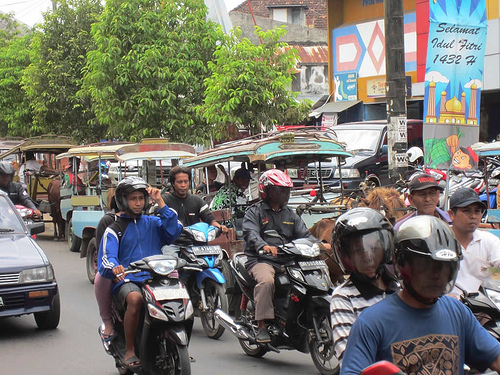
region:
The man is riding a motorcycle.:
[211, 167, 354, 369]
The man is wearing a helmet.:
[255, 165, 298, 215]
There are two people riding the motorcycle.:
[88, 172, 213, 374]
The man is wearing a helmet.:
[111, 178, 153, 218]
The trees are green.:
[0, 0, 306, 141]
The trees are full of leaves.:
[0, 1, 315, 151]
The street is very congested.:
[1, 135, 496, 373]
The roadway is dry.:
[0, 238, 322, 372]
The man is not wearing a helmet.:
[168, 162, 208, 200]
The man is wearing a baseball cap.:
[452, 187, 494, 232]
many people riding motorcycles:
[55, 139, 488, 351]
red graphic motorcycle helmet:
[237, 166, 290, 213]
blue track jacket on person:
[107, 197, 186, 287]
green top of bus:
[233, 134, 360, 164]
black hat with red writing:
[405, 168, 447, 213]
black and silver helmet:
[393, 209, 463, 306]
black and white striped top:
[328, 284, 355, 346]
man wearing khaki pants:
[237, 261, 283, 336]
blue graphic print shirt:
[353, 298, 488, 373]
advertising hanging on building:
[425, 16, 482, 86]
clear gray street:
[20, 328, 95, 361]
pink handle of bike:
[363, 351, 411, 373]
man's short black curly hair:
[162, 164, 207, 181]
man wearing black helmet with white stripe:
[104, 176, 171, 211]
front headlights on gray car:
[5, 264, 59, 284]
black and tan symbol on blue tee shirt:
[385, 329, 483, 373]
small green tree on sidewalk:
[185, 26, 319, 138]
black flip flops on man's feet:
[116, 349, 158, 374]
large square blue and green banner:
[403, 11, 485, 196]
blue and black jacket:
[80, 193, 255, 283]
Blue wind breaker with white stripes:
[103, 215, 185, 284]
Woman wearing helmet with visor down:
[329, 207, 398, 353]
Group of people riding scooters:
[43, 148, 386, 373]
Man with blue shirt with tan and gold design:
[370, 297, 469, 372]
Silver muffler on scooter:
[208, 300, 256, 366]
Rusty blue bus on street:
[191, 114, 347, 221]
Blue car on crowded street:
[1, 204, 63, 355]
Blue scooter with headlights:
[188, 215, 249, 315]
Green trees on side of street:
[9, 72, 249, 148]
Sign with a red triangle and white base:
[354, 15, 419, 102]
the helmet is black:
[400, 211, 468, 268]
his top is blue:
[106, 210, 182, 287]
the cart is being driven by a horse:
[324, 191, 406, 265]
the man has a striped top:
[332, 288, 350, 350]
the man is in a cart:
[201, 160, 248, 211]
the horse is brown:
[327, 188, 422, 244]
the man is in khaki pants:
[247, 271, 283, 324]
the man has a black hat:
[446, 193, 494, 219]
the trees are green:
[81, 42, 251, 91]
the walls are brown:
[307, 4, 324, 22]